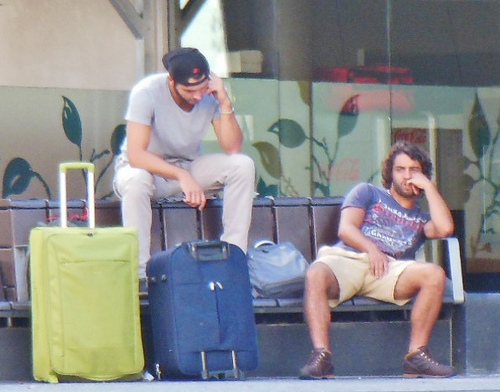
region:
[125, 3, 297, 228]
MAN TALKING ON CELLPHONE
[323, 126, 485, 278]
MAN SITTING ON BENCH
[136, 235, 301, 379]
BLUE SUITCASE IN FRONT OF BENCH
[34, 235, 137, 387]
YELLOW SUITCASE IN FRONT OF BENCH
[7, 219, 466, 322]
DARK CUSHIONS ON BENCH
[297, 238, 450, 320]
YELLOW SHORTS ON MAN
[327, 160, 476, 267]
GRAY SHIRT ON MAN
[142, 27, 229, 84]
BACKWARDS HAT ON MAN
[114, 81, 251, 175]
WHITE SHIRT ON MAN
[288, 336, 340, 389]
BROWN SHOES ON MAN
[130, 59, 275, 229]
man on cell phone on bench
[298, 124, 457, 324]
man sitting on bench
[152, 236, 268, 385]
blue suitcase in front of bench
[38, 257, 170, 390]
yellow suitcase in front of bench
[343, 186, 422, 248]
gray t shirt on man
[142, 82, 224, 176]
white t shirt on man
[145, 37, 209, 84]
backwards hat on man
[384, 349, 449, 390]
brown shoes on man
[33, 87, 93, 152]
green leave on wall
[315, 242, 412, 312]
yellow shorts on man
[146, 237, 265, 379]
A blue suitcase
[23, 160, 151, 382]
A yellow suitcase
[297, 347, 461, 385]
A man's brown shoes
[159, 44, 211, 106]
A man wearing a black cap backward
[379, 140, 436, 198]
A man with dark brown hair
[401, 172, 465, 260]
A man's elbow resting on the arm of a bench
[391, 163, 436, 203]
A man resting his head on his hand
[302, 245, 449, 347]
A man wearing light colored shorts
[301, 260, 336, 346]
A man's leg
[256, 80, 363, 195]
Green leaves painted on a wall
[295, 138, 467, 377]
a man sitting on a bench seat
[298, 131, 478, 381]
the man is leaning on the chair arm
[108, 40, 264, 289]
a man sitting on the back of the bench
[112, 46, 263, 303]
the man has his feet on the seat bench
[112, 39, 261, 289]
the man with the baseball cap on talks on a cellphone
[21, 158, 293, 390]
luggage in front of the bench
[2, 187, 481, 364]
a long metal bench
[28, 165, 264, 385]
two suitcases on the ground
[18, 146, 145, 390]
the suitcase on the left is yellow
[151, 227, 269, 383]
the suitcase on the right is blue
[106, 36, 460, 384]
Two men sitting on a bench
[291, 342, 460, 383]
Feet in brown leather boots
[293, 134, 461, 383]
A man sitting and leaning on his hand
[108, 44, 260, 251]
A man talking on a mobile phone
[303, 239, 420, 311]
Tan shorts on a seated man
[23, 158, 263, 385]
Two large pieces of luggage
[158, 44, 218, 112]
A man wearing a backwards cap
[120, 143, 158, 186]
An elbow resting on a knee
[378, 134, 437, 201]
A man with his fingers in his mouth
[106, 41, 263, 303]
A man sitting on the back of a bench